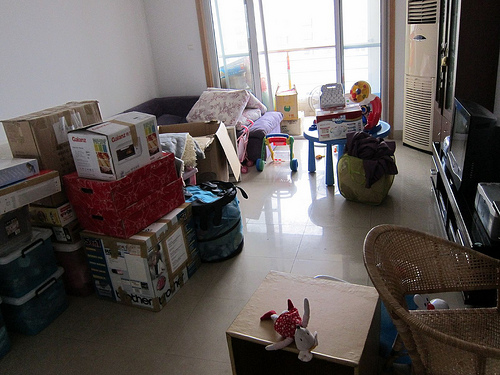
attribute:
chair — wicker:
[355, 222, 499, 373]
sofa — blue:
[116, 94, 203, 127]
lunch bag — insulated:
[314, 75, 351, 112]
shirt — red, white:
[272, 303, 308, 345]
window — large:
[201, 3, 399, 130]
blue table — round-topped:
[305, 126, 319, 142]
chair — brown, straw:
[356, 234, 423, 289]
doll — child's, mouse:
[259, 297, 320, 361]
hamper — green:
[334, 151, 397, 202]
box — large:
[101, 202, 202, 313]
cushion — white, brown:
[184, 85, 264, 124]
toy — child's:
[257, 127, 299, 172]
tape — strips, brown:
[141, 225, 161, 253]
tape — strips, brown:
[153, 214, 178, 224]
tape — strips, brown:
[173, 200, 194, 208]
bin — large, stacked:
[6, 290, 70, 335]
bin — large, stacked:
[3, 236, 60, 296]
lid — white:
[10, 269, 100, 307]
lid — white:
[1, 228, 52, 268]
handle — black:
[34, 275, 59, 295]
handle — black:
[19, 236, 50, 257]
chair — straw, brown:
[355, 221, 485, 370]